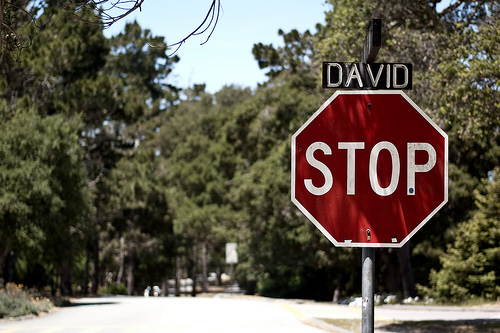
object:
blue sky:
[189, 50, 241, 78]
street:
[2, 293, 498, 330]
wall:
[204, 133, 275, 194]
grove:
[0, 0, 499, 308]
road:
[97, 300, 259, 329]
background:
[26, 5, 478, 309]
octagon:
[291, 90, 450, 249]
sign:
[318, 61, 416, 91]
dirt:
[388, 320, 494, 329]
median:
[300, 312, 495, 322]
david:
[321, 61, 413, 89]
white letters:
[303, 141, 436, 197]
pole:
[359, 248, 376, 333]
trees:
[146, 84, 250, 294]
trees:
[0, 89, 97, 306]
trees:
[65, 1, 173, 294]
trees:
[426, 166, 498, 300]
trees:
[218, 81, 289, 289]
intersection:
[94, 300, 301, 331]